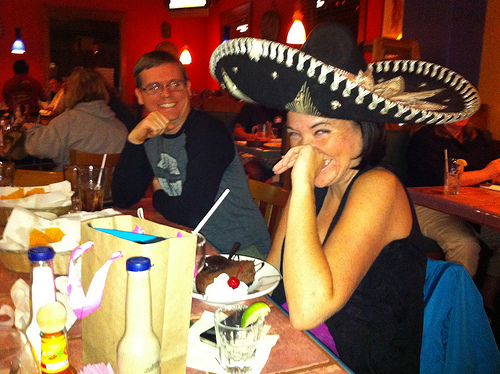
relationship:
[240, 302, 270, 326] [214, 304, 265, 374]
lime on glass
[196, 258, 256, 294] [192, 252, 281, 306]
cake on plate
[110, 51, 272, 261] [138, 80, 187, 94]
man wearing glasses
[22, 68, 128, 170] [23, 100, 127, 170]
person wearing hoodie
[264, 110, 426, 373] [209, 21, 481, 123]
woman wearing sombrero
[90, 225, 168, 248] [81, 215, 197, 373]
gift in bag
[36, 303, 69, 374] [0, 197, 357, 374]
bottle on table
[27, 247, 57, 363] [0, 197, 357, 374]
salt shaker on table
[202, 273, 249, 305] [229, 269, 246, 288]
whipped cream under cherry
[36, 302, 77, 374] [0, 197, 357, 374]
bottle on table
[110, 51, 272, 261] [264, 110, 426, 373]
man smiling at woman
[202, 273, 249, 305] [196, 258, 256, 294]
whipped cream next to cake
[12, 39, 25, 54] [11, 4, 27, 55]
shade on lamp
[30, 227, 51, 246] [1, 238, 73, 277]
tortilla chip in basket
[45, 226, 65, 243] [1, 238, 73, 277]
tortilla chip in basket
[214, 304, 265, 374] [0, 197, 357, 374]
glass on table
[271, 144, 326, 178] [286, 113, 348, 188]
hand covering face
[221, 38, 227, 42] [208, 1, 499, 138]
light on wall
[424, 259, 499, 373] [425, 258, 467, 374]
windbreaker on chair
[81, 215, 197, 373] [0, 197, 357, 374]
bag on table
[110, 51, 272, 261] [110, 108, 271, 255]
man wearing shirt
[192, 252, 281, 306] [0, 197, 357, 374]
plate on table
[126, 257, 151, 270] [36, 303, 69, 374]
lid on bottle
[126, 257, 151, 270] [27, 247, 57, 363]
lid on salt shaker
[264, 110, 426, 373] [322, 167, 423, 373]
woman wearing dress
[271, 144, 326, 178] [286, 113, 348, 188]
hand next to face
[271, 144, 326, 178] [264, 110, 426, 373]
hand of woman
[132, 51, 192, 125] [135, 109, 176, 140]
head in hand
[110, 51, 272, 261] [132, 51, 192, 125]
man resting head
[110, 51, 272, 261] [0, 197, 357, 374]
man sitting at table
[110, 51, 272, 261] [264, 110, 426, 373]
man next to woman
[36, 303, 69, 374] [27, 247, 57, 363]
bottle next to salt shaker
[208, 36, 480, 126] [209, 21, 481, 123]
trim on sombrero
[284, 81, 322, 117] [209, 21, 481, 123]
embroidery on sombrero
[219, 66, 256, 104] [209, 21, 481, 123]
embroidery on sombrero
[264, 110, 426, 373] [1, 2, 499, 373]
woman in restaurant